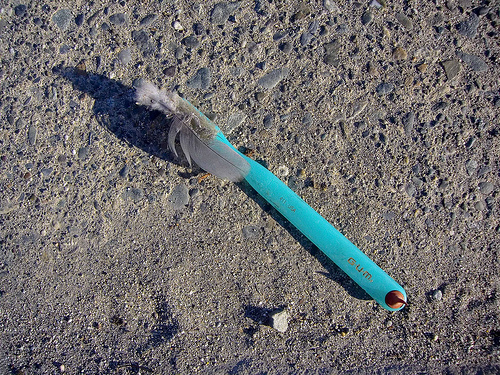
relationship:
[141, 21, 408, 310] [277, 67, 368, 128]
toothbrush on surface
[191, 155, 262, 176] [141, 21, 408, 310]
feather covering toothbrush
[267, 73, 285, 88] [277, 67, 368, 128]
spot on surface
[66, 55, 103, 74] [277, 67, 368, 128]
sand on surface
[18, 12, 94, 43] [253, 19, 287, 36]
pebble in dirt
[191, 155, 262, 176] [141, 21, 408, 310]
feather on toothbrush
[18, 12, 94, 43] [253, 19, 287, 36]
pebble on dirt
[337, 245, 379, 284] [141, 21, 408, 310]
lettering on toothbrush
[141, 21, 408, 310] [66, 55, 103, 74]
toothbrush in sand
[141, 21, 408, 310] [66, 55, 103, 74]
toothbrush on sand